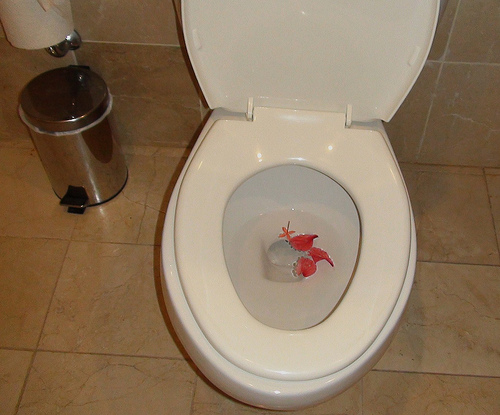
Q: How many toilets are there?
A: 1.